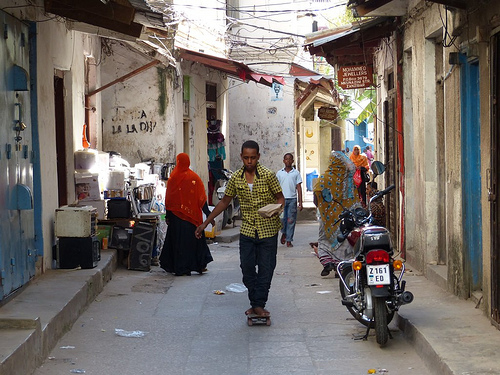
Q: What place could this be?
A: It is a street.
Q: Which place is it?
A: It is a street.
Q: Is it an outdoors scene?
A: Yes, it is outdoors.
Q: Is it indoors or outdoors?
A: It is outdoors.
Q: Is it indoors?
A: No, it is outdoors.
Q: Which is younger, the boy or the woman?
A: The boy is younger than the woman.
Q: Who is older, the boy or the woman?
A: The woman is older than the boy.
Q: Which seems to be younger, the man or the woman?
A: The man is younger than the woman.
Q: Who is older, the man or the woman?
A: The woman is older than the man.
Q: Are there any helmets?
A: No, there are no helmets.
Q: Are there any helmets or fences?
A: No, there are no helmets or fences.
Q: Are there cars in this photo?
A: No, there are no cars.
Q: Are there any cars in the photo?
A: No, there are no cars.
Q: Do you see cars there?
A: No, there are no cars.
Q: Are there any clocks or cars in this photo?
A: No, there are no cars or clocks.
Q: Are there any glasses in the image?
A: No, there are no glasses.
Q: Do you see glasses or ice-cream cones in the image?
A: No, there are no glasses or ice-cream cones.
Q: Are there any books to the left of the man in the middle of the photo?
A: Yes, there is a book to the left of the man.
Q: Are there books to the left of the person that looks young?
A: Yes, there is a book to the left of the man.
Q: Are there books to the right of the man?
A: No, the book is to the left of the man.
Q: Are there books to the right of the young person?
A: No, the book is to the left of the man.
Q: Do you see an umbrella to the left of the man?
A: No, there is a book to the left of the man.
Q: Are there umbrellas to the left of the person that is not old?
A: No, there is a book to the left of the man.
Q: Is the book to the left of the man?
A: Yes, the book is to the left of the man.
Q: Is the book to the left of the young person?
A: Yes, the book is to the left of the man.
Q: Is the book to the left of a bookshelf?
A: No, the book is to the left of the man.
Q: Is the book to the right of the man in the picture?
A: No, the book is to the left of the man.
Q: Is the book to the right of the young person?
A: No, the book is to the left of the man.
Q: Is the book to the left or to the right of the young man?
A: The book is to the left of the man.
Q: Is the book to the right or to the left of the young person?
A: The book is to the left of the man.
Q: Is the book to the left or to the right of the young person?
A: The book is to the left of the man.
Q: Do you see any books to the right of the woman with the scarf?
A: Yes, there is a book to the right of the woman.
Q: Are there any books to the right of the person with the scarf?
A: Yes, there is a book to the right of the woman.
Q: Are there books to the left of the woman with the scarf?
A: No, the book is to the right of the woman.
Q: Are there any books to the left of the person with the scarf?
A: No, the book is to the right of the woman.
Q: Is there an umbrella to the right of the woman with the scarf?
A: No, there is a book to the right of the woman.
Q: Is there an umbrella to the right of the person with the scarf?
A: No, there is a book to the right of the woman.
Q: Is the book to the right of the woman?
A: Yes, the book is to the right of the woman.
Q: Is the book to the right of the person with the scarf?
A: Yes, the book is to the right of the woman.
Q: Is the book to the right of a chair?
A: No, the book is to the right of the woman.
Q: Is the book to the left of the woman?
A: No, the book is to the right of the woman.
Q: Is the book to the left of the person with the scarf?
A: No, the book is to the right of the woman.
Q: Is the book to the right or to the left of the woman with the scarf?
A: The book is to the right of the woman.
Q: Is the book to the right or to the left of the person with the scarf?
A: The book is to the right of the woman.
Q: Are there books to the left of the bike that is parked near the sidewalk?
A: Yes, there is a book to the left of the bike.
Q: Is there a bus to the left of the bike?
A: No, there is a book to the left of the bike.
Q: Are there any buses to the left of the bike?
A: No, there is a book to the left of the bike.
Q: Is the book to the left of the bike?
A: Yes, the book is to the left of the bike.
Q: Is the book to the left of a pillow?
A: No, the book is to the left of the bike.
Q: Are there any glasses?
A: No, there are no glasses.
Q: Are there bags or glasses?
A: No, there are no glasses or bags.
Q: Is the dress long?
A: Yes, the dress is long.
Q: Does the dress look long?
A: Yes, the dress is long.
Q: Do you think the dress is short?
A: No, the dress is long.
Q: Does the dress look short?
A: No, the dress is long.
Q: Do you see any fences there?
A: No, there are no fences.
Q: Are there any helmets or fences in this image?
A: No, there are no fences or helmets.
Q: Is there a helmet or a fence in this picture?
A: No, there are no fences or helmets.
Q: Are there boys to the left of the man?
A: Yes, there is a boy to the left of the man.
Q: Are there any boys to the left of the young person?
A: Yes, there is a boy to the left of the man.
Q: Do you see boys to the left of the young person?
A: Yes, there is a boy to the left of the man.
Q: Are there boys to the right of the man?
A: No, the boy is to the left of the man.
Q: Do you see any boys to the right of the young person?
A: No, the boy is to the left of the man.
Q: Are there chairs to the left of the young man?
A: No, there is a boy to the left of the man.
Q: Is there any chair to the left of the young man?
A: No, there is a boy to the left of the man.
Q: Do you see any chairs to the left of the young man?
A: No, there is a boy to the left of the man.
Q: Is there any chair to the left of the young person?
A: No, there is a boy to the left of the man.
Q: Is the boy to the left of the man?
A: Yes, the boy is to the left of the man.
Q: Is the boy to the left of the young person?
A: Yes, the boy is to the left of the man.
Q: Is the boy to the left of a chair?
A: No, the boy is to the left of the man.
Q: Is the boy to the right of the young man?
A: No, the boy is to the left of the man.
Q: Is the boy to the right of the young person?
A: No, the boy is to the left of the man.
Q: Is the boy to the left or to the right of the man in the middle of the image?
A: The boy is to the left of the man.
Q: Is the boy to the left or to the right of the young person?
A: The boy is to the left of the man.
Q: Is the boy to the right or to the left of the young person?
A: The boy is to the left of the man.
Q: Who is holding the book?
A: The boy is holding the book.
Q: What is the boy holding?
A: The boy is holding the book.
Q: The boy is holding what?
A: The boy is holding the book.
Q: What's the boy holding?
A: The boy is holding the book.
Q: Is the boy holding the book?
A: Yes, the boy is holding the book.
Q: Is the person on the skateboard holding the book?
A: Yes, the boy is holding the book.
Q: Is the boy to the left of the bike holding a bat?
A: No, the boy is holding the book.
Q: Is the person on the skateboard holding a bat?
A: No, the boy is holding the book.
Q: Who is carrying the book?
A: The boy is carrying the book.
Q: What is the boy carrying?
A: The boy is carrying a book.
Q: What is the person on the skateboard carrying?
A: The boy is carrying a book.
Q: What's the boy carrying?
A: The boy is carrying a book.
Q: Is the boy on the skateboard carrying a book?
A: Yes, the boy is carrying a book.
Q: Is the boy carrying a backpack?
A: No, the boy is carrying a book.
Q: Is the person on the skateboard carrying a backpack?
A: No, the boy is carrying a book.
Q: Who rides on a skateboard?
A: The boy rides on a skateboard.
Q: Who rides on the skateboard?
A: The boy rides on a skateboard.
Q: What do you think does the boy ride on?
A: The boy rides on a skateboard.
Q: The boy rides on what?
A: The boy rides on a skateboard.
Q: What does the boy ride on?
A: The boy rides on a skateboard.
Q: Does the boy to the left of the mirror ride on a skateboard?
A: Yes, the boy rides on a skateboard.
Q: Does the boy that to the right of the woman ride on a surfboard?
A: No, the boy rides on a skateboard.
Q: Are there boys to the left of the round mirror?
A: Yes, there is a boy to the left of the mirror.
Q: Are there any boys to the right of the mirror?
A: No, the boy is to the left of the mirror.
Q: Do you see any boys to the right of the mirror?
A: No, the boy is to the left of the mirror.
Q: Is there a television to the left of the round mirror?
A: No, there is a boy to the left of the mirror.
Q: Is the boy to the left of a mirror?
A: Yes, the boy is to the left of a mirror.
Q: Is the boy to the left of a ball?
A: No, the boy is to the left of a mirror.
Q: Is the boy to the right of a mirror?
A: No, the boy is to the left of a mirror.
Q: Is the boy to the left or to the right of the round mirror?
A: The boy is to the left of the mirror.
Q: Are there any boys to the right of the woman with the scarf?
A: Yes, there is a boy to the right of the woman.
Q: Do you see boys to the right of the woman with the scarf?
A: Yes, there is a boy to the right of the woman.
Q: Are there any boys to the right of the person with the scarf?
A: Yes, there is a boy to the right of the woman.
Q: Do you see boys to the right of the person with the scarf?
A: Yes, there is a boy to the right of the woman.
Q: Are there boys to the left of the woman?
A: No, the boy is to the right of the woman.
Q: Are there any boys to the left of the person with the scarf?
A: No, the boy is to the right of the woman.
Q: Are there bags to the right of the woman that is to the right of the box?
A: No, there is a boy to the right of the woman.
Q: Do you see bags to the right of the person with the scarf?
A: No, there is a boy to the right of the woman.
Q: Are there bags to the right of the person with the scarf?
A: No, there is a boy to the right of the woman.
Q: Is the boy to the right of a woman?
A: Yes, the boy is to the right of a woman.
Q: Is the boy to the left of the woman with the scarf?
A: No, the boy is to the right of the woman.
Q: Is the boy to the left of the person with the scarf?
A: No, the boy is to the right of the woman.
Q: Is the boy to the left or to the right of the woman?
A: The boy is to the right of the woman.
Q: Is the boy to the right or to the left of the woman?
A: The boy is to the right of the woman.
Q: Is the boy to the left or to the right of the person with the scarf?
A: The boy is to the right of the woman.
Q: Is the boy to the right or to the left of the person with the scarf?
A: The boy is to the right of the woman.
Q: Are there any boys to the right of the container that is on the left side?
A: Yes, there is a boy to the right of the box.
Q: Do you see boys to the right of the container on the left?
A: Yes, there is a boy to the right of the box.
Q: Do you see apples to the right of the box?
A: No, there is a boy to the right of the box.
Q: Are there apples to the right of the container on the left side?
A: No, there is a boy to the right of the box.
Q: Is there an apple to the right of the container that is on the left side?
A: No, there is a boy to the right of the box.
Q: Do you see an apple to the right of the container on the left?
A: No, there is a boy to the right of the box.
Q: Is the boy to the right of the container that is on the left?
A: Yes, the boy is to the right of the box.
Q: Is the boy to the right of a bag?
A: No, the boy is to the right of the box.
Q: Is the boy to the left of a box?
A: No, the boy is to the right of a box.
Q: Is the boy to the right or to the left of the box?
A: The boy is to the right of the box.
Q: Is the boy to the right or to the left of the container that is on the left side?
A: The boy is to the right of the box.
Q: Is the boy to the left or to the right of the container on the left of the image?
A: The boy is to the right of the box.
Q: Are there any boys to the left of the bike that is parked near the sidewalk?
A: Yes, there is a boy to the left of the bike.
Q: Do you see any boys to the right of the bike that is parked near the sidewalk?
A: No, the boy is to the left of the bike.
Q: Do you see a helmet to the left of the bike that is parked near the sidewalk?
A: No, there is a boy to the left of the bike.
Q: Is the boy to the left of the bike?
A: Yes, the boy is to the left of the bike.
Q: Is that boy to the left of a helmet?
A: No, the boy is to the left of the bike.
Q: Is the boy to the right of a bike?
A: No, the boy is to the left of a bike.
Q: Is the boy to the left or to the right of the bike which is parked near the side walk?
A: The boy is to the left of the bike.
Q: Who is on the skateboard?
A: The boy is on the skateboard.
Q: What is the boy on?
A: The boy is on the skateboard.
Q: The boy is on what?
A: The boy is on the skateboard.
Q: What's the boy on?
A: The boy is on the skateboard.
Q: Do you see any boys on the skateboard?
A: Yes, there is a boy on the skateboard.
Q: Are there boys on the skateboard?
A: Yes, there is a boy on the skateboard.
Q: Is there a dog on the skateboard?
A: No, there is a boy on the skateboard.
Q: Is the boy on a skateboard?
A: Yes, the boy is on a skateboard.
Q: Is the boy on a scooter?
A: No, the boy is on a skateboard.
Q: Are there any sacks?
A: No, there are no sacks.